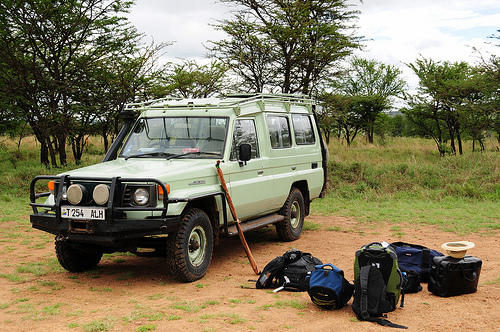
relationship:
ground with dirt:
[0, 130, 499, 330] [95, 267, 296, 329]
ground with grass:
[0, 130, 499, 330] [319, 169, 490, 223]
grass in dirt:
[126, 287, 195, 329] [0, 210, 498, 330]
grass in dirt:
[303, 217, 382, 235] [0, 210, 498, 330]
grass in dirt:
[389, 221, 409, 239] [0, 210, 498, 330]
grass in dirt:
[6, 253, 66, 291] [0, 210, 498, 330]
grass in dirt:
[1, 216, 53, 253] [0, 210, 498, 330]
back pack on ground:
[304, 263, 356, 311] [0, 130, 499, 330]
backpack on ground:
[353, 241, 407, 307] [0, 130, 499, 330]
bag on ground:
[389, 239, 444, 281] [0, 130, 499, 330]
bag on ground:
[255, 247, 302, 286] [0, 130, 499, 330]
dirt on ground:
[0, 210, 498, 330] [1, 171, 498, 330]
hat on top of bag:
[441, 240, 476, 258] [426, 256, 482, 288]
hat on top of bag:
[441, 240, 476, 258] [429, 255, 482, 296]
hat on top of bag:
[434, 230, 491, 265] [427, 244, 492, 305]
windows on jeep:
[263, 116, 323, 148] [58, 65, 333, 277]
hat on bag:
[441, 240, 476, 258] [429, 255, 482, 296]